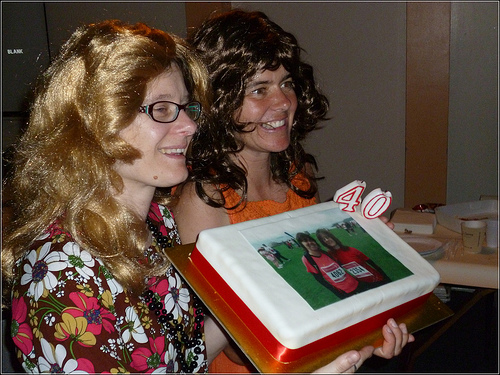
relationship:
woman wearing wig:
[18, 57, 200, 374] [29, 23, 156, 253]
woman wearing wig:
[225, 64, 322, 214] [192, 13, 320, 198]